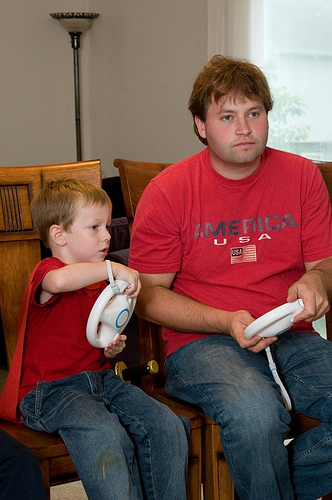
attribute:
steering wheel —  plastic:
[239, 294, 316, 346]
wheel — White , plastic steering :
[86, 278, 138, 349]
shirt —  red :
[11, 253, 135, 436]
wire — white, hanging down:
[265, 341, 292, 408]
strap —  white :
[103, 259, 119, 285]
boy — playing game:
[1, 175, 189, 498]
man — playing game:
[126, 53, 330, 498]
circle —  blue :
[113, 307, 130, 326]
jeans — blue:
[17, 367, 191, 498]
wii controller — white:
[86, 280, 136, 347]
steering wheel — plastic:
[87, 278, 144, 361]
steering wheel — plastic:
[239, 293, 303, 344]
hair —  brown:
[185, 53, 273, 104]